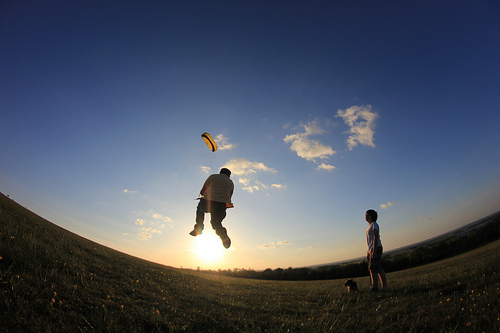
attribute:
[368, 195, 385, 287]
woman — standing, young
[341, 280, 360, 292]
dog — little, here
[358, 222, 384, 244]
t-shirt — white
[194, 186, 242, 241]
man — in air, airborne, standing, jumping, outdoors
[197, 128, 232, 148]
kite — yellow, shape, black, flying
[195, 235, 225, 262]
sun — glaring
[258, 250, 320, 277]
tree — green, line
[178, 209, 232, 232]
jeans — blue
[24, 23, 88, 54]
sky — blue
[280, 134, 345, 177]
clouds — white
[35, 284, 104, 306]
flowers — yellow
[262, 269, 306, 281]
trees — background